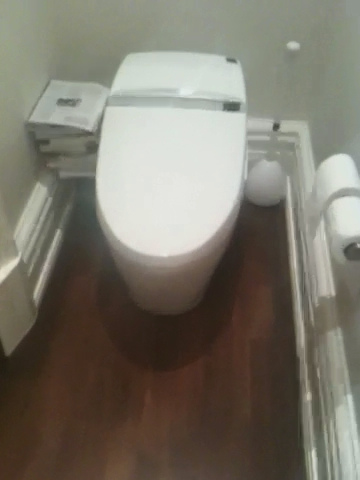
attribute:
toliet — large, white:
[97, 51, 250, 317]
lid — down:
[93, 106, 247, 254]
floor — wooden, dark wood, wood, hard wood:
[1, 199, 303, 479]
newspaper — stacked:
[27, 69, 111, 180]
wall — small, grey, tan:
[0, 1, 359, 442]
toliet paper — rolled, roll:
[302, 151, 359, 272]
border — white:
[2, 116, 359, 478]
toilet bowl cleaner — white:
[243, 120, 287, 209]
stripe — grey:
[106, 91, 245, 114]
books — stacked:
[43, 141, 98, 182]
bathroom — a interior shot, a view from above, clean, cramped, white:
[2, 2, 357, 479]